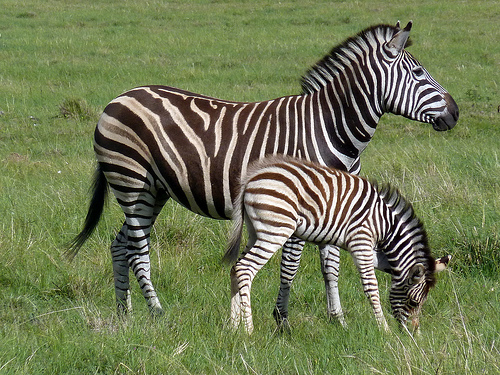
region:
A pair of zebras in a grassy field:
[44, 14, 467, 346]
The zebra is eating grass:
[207, 143, 454, 342]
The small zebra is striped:
[208, 133, 458, 353]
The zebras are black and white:
[62, 15, 457, 358]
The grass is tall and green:
[7, 64, 493, 366]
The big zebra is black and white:
[32, 15, 468, 332]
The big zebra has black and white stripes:
[46, 21, 460, 314]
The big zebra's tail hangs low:
[35, 129, 126, 278]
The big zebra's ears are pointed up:
[374, 18, 416, 71]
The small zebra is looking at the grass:
[365, 170, 457, 355]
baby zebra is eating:
[227, 162, 461, 372]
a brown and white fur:
[73, 72, 338, 206]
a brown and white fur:
[233, 64, 357, 164]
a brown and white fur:
[291, 60, 398, 177]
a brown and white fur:
[88, 83, 218, 224]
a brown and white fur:
[233, 155, 407, 308]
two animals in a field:
[30, 10, 481, 355]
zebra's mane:
[321, 42, 351, 62]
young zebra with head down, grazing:
[232, 150, 444, 345]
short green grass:
[111, 6, 277, 56]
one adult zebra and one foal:
[45, 11, 470, 341]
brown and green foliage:
[1, 210, 48, 337]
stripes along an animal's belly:
[176, 160, 226, 205]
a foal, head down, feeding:
[355, 175, 455, 350]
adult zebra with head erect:
[255, 10, 465, 155]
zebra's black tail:
[78, 192, 98, 242]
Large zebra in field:
[55, 31, 443, 166]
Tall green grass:
[19, 297, 264, 364]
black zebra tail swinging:
[70, 163, 109, 257]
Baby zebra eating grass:
[222, 151, 441, 350]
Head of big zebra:
[292, 9, 466, 133]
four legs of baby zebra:
[228, 245, 392, 351]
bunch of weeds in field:
[40, 85, 93, 125]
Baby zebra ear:
[433, 255, 457, 273]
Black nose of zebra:
[431, 85, 467, 130]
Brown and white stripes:
[261, 171, 316, 215]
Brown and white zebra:
[56, 22, 466, 326]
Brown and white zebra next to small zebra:
[61, 17, 463, 328]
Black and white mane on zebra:
[298, 14, 416, 97]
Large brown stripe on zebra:
[117, 87, 210, 224]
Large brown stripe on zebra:
[225, 101, 266, 209]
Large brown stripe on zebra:
[248, 167, 320, 233]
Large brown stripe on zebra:
[277, 159, 326, 214]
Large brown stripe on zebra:
[328, 173, 359, 244]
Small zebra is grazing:
[218, 156, 451, 351]